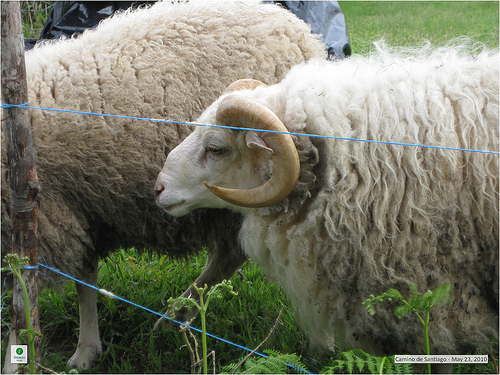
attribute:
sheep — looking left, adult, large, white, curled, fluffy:
[150, 32, 499, 372]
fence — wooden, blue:
[7, 6, 500, 375]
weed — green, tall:
[161, 273, 457, 365]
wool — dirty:
[16, 0, 323, 361]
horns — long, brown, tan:
[191, 73, 303, 220]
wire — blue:
[4, 99, 498, 373]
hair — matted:
[253, 41, 500, 362]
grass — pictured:
[82, 263, 268, 361]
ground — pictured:
[0, 290, 500, 372]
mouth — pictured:
[153, 195, 186, 215]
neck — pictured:
[260, 87, 319, 216]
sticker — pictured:
[6, 340, 31, 366]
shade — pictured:
[45, 286, 261, 365]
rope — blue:
[30, 257, 305, 373]